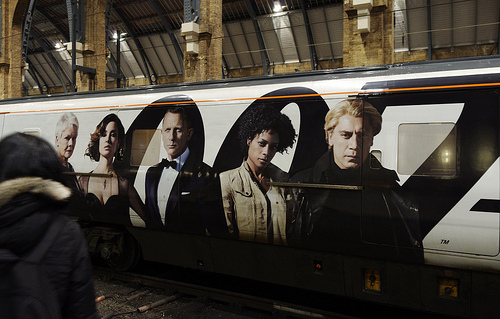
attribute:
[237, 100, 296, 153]
hair — black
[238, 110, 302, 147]
hair — black, curly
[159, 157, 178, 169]
bowtie — black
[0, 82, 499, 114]
stripe — orange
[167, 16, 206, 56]
light — off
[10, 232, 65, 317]
backpack — black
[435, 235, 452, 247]
trademark — small, black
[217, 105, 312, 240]
woman — African American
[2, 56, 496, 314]
train — white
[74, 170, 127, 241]
dress — low cut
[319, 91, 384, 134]
hair — blonde